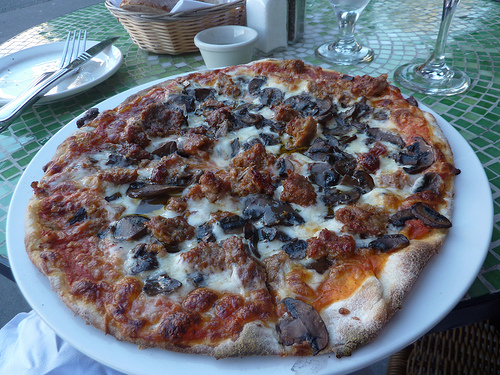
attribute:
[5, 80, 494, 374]
white plate — round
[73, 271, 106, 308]
cheese — scorched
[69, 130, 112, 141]
cheese — scorched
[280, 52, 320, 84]
cheese — scorched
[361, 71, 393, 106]
cheese — scorched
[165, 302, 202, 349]
cheese — scorched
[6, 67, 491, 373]
dish — white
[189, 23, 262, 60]
cup — small, for dipping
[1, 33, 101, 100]
plate — round, white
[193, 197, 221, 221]
cheese — melted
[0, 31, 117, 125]
utensils — silver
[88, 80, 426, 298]
cheese — melted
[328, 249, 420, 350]
crust — brown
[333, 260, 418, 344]
crust — brown , blistered 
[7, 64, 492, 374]
plate — white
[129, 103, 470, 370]
pizza — sliced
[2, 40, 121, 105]
plate — small, white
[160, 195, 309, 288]
sauce — red